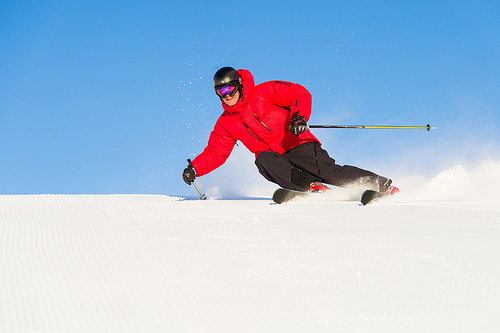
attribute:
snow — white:
[0, 27, 499, 332]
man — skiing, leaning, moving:
[183, 66, 401, 204]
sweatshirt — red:
[190, 69, 322, 158]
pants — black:
[254, 141, 392, 194]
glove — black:
[289, 116, 307, 137]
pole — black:
[309, 125, 438, 132]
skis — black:
[273, 185, 391, 206]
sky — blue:
[0, 0, 499, 195]